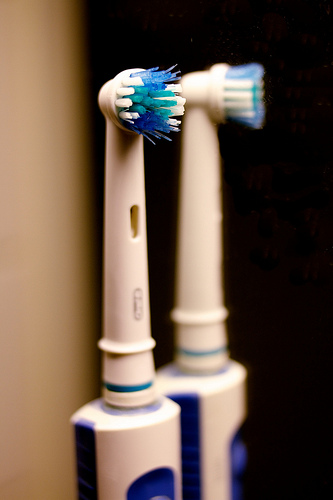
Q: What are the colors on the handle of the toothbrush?
A: Blue and white.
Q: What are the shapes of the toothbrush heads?
A: Circle.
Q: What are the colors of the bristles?
A: Blue and white.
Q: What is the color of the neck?
A: White.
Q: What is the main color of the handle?
A: White.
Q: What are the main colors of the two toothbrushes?
A: Blue and white.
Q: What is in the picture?
A: Toothbrushes.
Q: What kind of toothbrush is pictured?
A: Electric toothbrush.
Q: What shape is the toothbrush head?
A: Round.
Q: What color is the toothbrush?
A: White.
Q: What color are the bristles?
A: Blue, white, green.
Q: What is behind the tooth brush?
A: Mirror.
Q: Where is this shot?
A: Bathroom.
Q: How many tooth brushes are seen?
A: 2.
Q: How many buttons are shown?
A: 1.